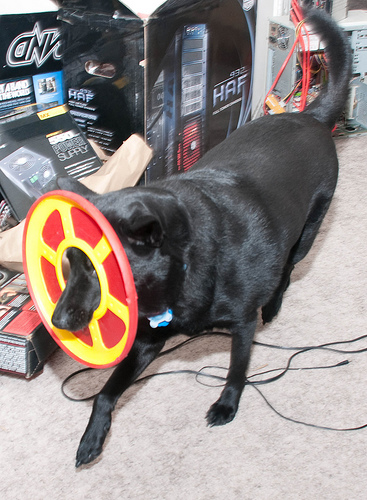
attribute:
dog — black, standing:
[121, 159, 296, 277]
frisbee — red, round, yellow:
[33, 204, 136, 277]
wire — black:
[302, 343, 338, 457]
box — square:
[8, 308, 37, 371]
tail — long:
[315, 17, 346, 107]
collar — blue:
[182, 247, 190, 281]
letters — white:
[54, 147, 95, 159]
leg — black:
[207, 316, 248, 439]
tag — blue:
[156, 313, 188, 329]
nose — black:
[51, 307, 83, 321]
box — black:
[104, 7, 201, 85]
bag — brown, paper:
[110, 130, 135, 184]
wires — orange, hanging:
[277, 32, 309, 96]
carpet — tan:
[328, 199, 364, 305]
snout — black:
[53, 284, 93, 324]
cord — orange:
[283, 63, 284, 105]